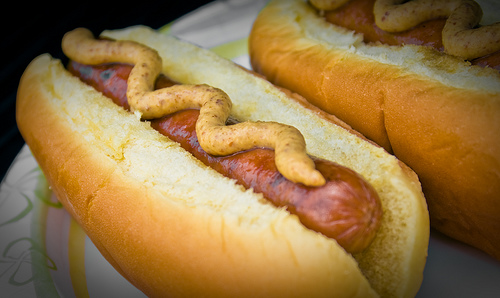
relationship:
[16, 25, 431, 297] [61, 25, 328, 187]
bun has mustard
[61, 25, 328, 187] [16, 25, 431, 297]
mustard on bun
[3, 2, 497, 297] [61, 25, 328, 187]
plate has mustard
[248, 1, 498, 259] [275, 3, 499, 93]
bun has edge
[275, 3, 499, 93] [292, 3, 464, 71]
edge has mustard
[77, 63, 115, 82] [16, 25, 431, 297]
grill mark on bun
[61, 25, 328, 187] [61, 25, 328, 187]
mustard has mustard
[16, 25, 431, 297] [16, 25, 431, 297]
bun on bun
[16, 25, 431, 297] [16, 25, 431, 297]
bun in bun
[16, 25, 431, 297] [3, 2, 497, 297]
bun on top of plate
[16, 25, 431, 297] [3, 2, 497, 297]
bun on plate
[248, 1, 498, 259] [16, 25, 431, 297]
bun in bun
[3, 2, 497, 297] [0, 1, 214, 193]
plate has edge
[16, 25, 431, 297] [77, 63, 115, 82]
bun has grill mark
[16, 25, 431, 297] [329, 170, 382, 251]
bun has end